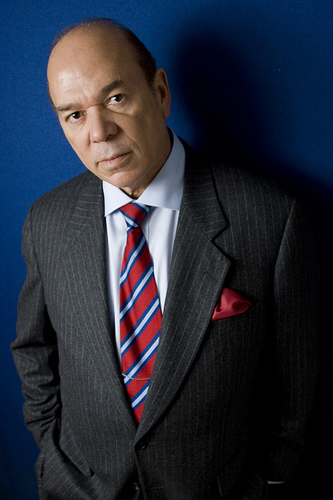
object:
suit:
[8, 135, 332, 500]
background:
[0, 0, 332, 187]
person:
[10, 16, 333, 500]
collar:
[103, 174, 182, 214]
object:
[213, 288, 254, 321]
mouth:
[96, 147, 134, 171]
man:
[12, 14, 322, 494]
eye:
[106, 88, 127, 106]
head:
[43, 17, 171, 192]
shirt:
[102, 127, 186, 426]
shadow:
[178, 43, 265, 152]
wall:
[0, 0, 332, 173]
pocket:
[212, 304, 263, 381]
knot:
[115, 203, 158, 227]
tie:
[115, 202, 163, 421]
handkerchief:
[212, 285, 251, 322]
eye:
[65, 109, 85, 122]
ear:
[153, 68, 171, 119]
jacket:
[8, 127, 333, 500]